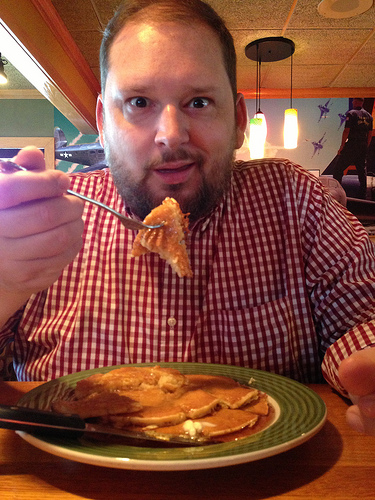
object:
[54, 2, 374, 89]
ceiling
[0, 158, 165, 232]
fork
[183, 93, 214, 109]
eye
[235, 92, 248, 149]
ear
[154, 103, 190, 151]
nose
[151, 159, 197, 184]
mouth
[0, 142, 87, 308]
hand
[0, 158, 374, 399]
shirt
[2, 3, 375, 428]
guy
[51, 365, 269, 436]
pancakes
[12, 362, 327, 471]
plate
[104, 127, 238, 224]
beard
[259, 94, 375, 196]
mural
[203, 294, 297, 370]
pocket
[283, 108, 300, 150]
light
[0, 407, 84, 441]
handle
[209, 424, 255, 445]
syrup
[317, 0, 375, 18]
speaker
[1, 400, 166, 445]
knife